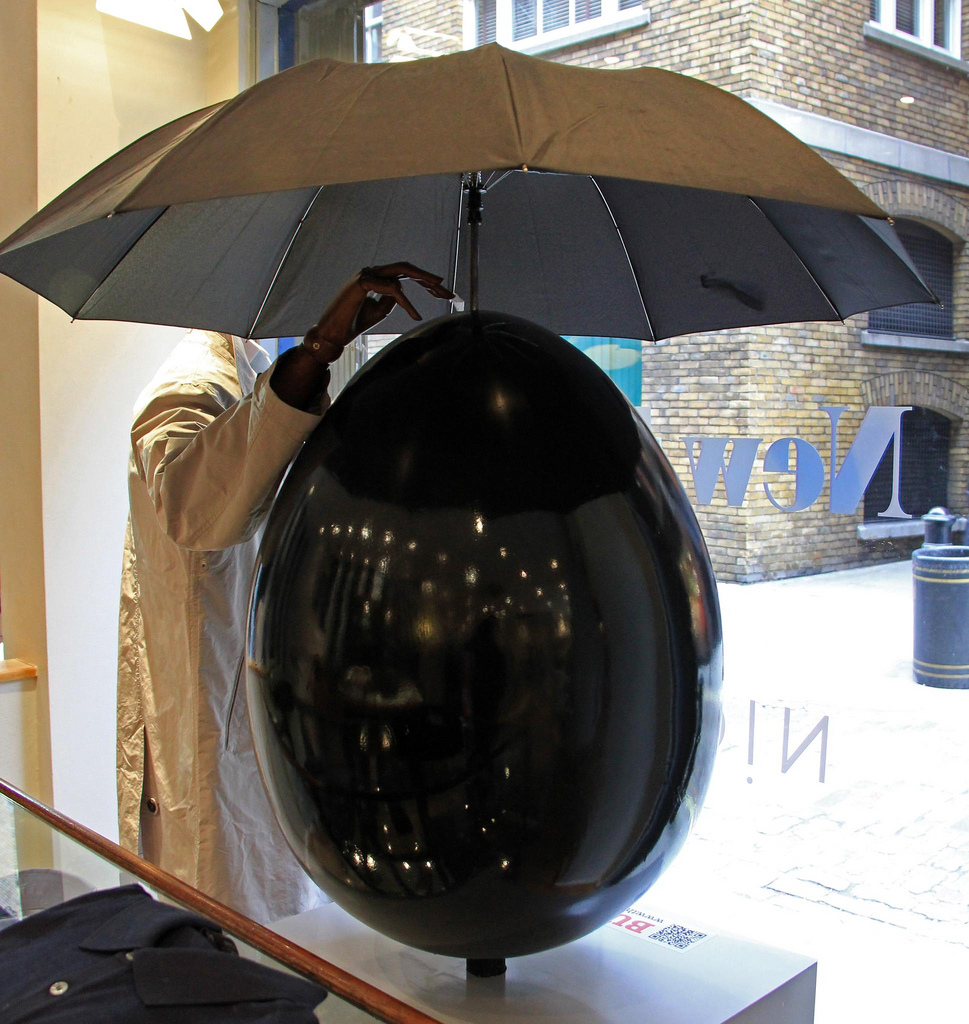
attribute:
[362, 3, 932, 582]
building — brick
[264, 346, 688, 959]
egg —  large,   black 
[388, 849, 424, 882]
light glare — small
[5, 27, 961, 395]
umbrella — open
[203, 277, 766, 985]
egg — black, big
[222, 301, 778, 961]
egg — black